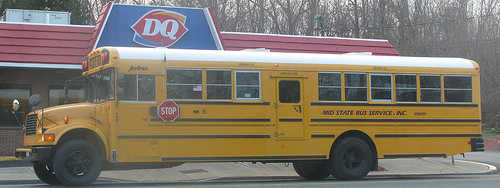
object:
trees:
[1, 2, 500, 59]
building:
[1, 3, 402, 155]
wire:
[239, 15, 500, 46]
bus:
[14, 46, 486, 186]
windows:
[84, 67, 473, 107]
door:
[276, 78, 307, 141]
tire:
[51, 137, 107, 187]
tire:
[328, 136, 376, 181]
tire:
[32, 145, 62, 187]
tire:
[292, 160, 332, 180]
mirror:
[28, 94, 42, 106]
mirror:
[12, 98, 21, 111]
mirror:
[62, 77, 71, 104]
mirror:
[105, 68, 119, 104]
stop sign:
[157, 99, 181, 123]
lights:
[38, 50, 479, 146]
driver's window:
[115, 73, 157, 102]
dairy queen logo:
[129, 9, 189, 48]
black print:
[322, 110, 427, 116]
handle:
[292, 105, 301, 113]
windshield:
[82, 67, 115, 104]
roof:
[1, 21, 399, 69]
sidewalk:
[3, 154, 497, 179]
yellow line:
[1, 159, 496, 184]